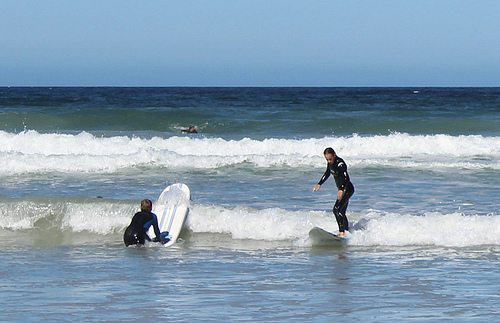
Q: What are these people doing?
A: Surfing.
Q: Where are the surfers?
A: In the ocean.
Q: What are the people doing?
A: Surfing.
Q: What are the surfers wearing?
A: Wetsuits.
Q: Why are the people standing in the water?
A: To surf.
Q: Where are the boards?
A: In the water.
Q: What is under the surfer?
A: A surfboard.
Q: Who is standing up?
A: A girl.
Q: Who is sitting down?
A: A boy.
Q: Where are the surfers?
A: In the ocean.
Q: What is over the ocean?
A: Blue sky.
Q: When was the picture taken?
A: Daytime.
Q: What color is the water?
A: Blue and white.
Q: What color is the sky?
A: Blue.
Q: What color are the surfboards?
A: White.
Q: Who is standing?
A: The person on the right.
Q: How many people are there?
A: Three.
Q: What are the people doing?
A: Surfing.